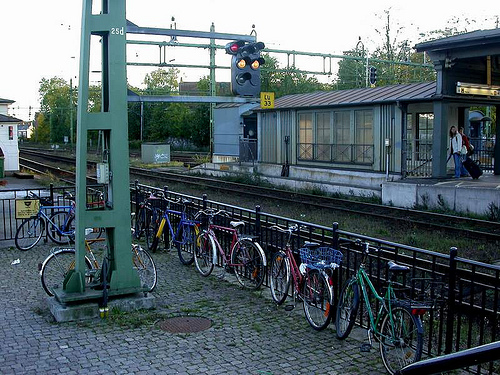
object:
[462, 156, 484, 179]
luggage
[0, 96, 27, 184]
house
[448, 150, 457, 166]
ground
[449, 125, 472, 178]
person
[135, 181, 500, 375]
railing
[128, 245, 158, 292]
tire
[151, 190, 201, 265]
bicycle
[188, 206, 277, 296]
bicycle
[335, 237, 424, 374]
greenbike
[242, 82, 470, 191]
house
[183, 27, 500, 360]
train station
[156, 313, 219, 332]
manhole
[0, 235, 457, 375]
platform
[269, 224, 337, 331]
bicycle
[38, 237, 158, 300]
bike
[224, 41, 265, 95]
signal light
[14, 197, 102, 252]
bike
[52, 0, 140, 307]
metal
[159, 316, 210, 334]
cover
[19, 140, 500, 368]
tracks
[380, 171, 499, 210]
platform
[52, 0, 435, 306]
structure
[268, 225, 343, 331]
bike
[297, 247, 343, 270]
basket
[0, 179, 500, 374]
fence